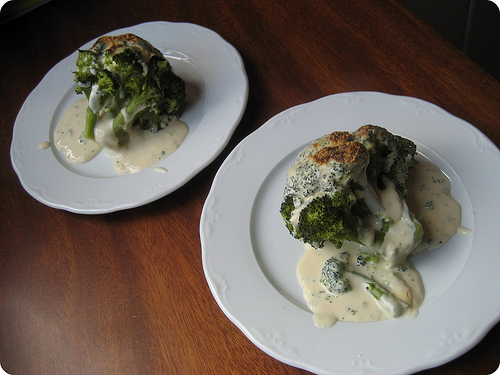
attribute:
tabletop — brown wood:
[4, 4, 499, 369]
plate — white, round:
[199, 90, 499, 374]